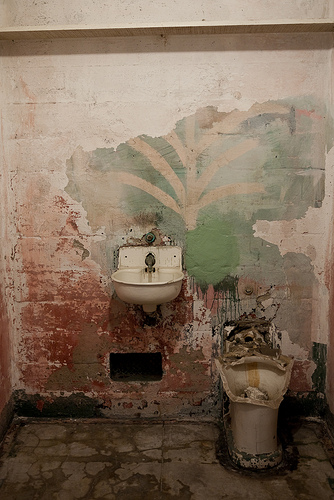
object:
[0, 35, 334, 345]
white bathroom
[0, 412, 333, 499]
floor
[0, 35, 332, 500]
bathroom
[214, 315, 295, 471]
toliet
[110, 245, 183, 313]
sink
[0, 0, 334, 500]
wall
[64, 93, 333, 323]
design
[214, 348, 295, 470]
toilet bowl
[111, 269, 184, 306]
bowl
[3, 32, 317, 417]
wall/hole